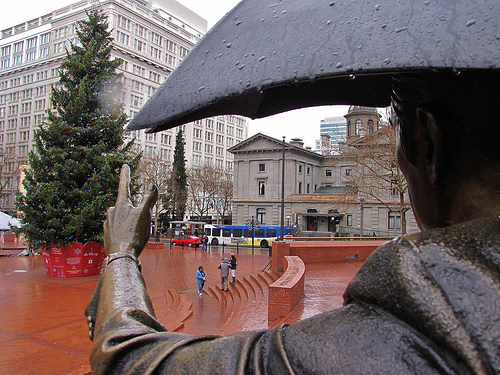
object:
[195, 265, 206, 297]
woman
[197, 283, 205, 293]
pants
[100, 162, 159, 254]
hand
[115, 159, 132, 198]
finger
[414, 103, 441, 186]
ear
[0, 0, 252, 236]
building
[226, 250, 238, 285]
woman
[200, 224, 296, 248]
bus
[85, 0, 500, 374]
bronze statue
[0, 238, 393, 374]
brick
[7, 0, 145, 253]
tree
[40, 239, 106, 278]
tree base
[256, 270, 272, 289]
stairs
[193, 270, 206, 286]
jacket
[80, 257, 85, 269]
red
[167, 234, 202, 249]
car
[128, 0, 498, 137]
umbrella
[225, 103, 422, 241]
building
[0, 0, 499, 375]
photo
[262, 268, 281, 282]
stairs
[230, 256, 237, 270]
coat